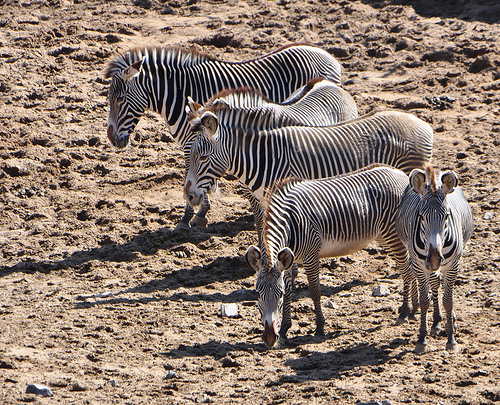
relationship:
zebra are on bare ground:
[100, 43, 343, 230] [1, 2, 499, 403]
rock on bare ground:
[220, 300, 242, 320] [1, 2, 499, 403]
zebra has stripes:
[100, 40, 349, 230] [112, 50, 343, 174]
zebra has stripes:
[397, 165, 476, 357] [411, 186, 461, 314]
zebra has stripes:
[243, 160, 421, 348] [259, 166, 415, 322]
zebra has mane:
[100, 40, 349, 230] [104, 44, 213, 80]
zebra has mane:
[243, 160, 421, 348] [260, 173, 302, 269]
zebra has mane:
[397, 165, 476, 357] [424, 168, 439, 193]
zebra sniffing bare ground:
[243, 160, 421, 348] [1, 2, 499, 403]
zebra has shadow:
[100, 40, 349, 230] [2, 210, 257, 282]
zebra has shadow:
[397, 165, 476, 357] [265, 331, 416, 390]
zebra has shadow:
[243, 160, 421, 348] [164, 329, 343, 362]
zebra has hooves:
[100, 40, 349, 230] [171, 216, 210, 233]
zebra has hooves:
[397, 165, 476, 357] [415, 326, 460, 358]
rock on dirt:
[220, 300, 242, 320] [1, 2, 499, 403]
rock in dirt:
[220, 300, 242, 320] [1, 2, 499, 403]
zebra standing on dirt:
[100, 40, 349, 230] [1, 2, 499, 403]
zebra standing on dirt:
[397, 165, 476, 357] [1, 2, 499, 403]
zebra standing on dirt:
[100, 43, 343, 230] [1, 2, 499, 403]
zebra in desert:
[100, 43, 343, 230] [1, 2, 499, 403]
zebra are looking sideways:
[100, 43, 343, 230] [100, 48, 286, 347]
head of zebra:
[103, 49, 152, 150] [100, 40, 349, 230]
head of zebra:
[182, 111, 228, 208] [178, 107, 436, 260]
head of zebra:
[253, 265, 292, 345] [243, 160, 421, 348]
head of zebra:
[409, 168, 459, 273] [397, 165, 476, 357]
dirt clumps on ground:
[5, 4, 500, 402] [1, 2, 499, 403]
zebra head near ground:
[246, 245, 297, 348] [1, 2, 499, 403]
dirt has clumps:
[1, 2, 499, 403] [5, 4, 500, 402]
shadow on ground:
[2, 210, 257, 282] [1, 2, 499, 403]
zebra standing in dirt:
[100, 43, 343, 230] [1, 2, 499, 403]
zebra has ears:
[397, 165, 476, 357] [406, 167, 459, 196]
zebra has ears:
[243, 160, 421, 348] [244, 243, 295, 270]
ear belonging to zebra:
[243, 243, 262, 273] [243, 160, 421, 348]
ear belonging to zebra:
[277, 247, 295, 271] [243, 160, 421, 348]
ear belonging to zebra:
[407, 166, 428, 195] [397, 165, 476, 357]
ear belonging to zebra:
[441, 170, 458, 194] [397, 165, 476, 357]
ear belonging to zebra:
[272, 244, 296, 273] [243, 160, 421, 348]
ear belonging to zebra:
[409, 169, 428, 195] [390, 160, 476, 355]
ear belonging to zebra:
[435, 166, 459, 194] [390, 160, 476, 355]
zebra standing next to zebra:
[100, 40, 349, 230] [184, 75, 359, 126]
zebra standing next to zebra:
[184, 75, 359, 126] [179, 102, 435, 202]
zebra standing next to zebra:
[179, 102, 435, 202] [243, 160, 421, 348]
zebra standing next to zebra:
[243, 160, 421, 348] [390, 160, 476, 355]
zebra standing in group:
[100, 40, 349, 230] [102, 36, 474, 354]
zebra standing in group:
[184, 75, 359, 126] [102, 36, 474, 354]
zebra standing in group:
[394, 163, 475, 355] [102, 36, 474, 354]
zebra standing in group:
[243, 160, 421, 348] [102, 36, 474, 354]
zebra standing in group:
[390, 160, 476, 355] [102, 36, 474, 354]